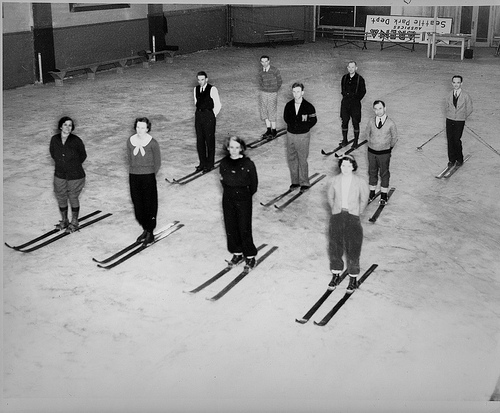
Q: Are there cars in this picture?
A: No, there are no cars.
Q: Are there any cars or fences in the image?
A: No, there are no cars or fences.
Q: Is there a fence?
A: No, there are no fences.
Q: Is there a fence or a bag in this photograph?
A: No, there are no fences or bags.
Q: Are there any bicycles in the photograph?
A: No, there are no bicycles.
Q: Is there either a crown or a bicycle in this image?
A: No, there are no bicycles or crowns.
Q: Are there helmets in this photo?
A: No, there are no helmets.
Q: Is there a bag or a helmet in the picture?
A: No, there are no helmets or bags.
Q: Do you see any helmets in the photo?
A: No, there are no helmets.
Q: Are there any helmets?
A: No, there are no helmets.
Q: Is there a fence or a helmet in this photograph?
A: No, there are no helmets or fences.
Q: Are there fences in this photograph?
A: No, there are no fences.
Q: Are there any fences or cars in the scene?
A: No, there are no fences or cars.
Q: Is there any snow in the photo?
A: Yes, there is snow.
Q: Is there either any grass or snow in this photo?
A: Yes, there is snow.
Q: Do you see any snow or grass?
A: Yes, there is snow.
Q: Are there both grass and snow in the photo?
A: No, there is snow but no grass.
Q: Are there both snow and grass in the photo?
A: No, there is snow but no grass.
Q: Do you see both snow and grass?
A: No, there is snow but no grass.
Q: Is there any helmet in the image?
A: No, there are no helmets.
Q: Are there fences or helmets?
A: No, there are no helmets or fences.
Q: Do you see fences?
A: No, there are no fences.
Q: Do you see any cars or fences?
A: No, there are no fences or cars.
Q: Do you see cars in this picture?
A: No, there are no cars.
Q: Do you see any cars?
A: No, there are no cars.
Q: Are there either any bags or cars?
A: No, there are no cars or bags.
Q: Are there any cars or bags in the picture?
A: No, there are no cars or bags.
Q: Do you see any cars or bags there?
A: No, there are no cars or bags.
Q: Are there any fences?
A: No, there are no fences.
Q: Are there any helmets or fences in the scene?
A: No, there are no fences or helmets.